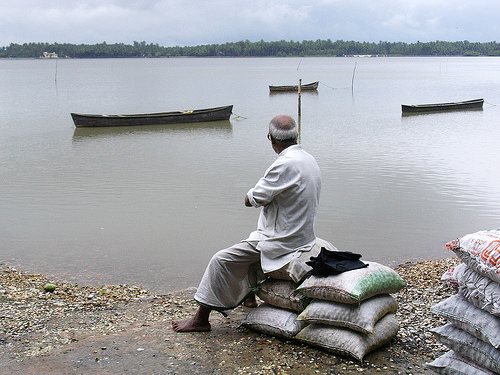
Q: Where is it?
A: This is at the lake.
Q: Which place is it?
A: It is a lake.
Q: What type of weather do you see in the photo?
A: It is cloudy.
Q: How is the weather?
A: It is cloudy.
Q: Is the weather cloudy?
A: Yes, it is cloudy.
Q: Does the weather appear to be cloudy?
A: Yes, it is cloudy.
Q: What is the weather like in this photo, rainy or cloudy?
A: It is cloudy.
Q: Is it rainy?
A: No, it is cloudy.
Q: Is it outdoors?
A: Yes, it is outdoors.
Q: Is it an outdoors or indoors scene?
A: It is outdoors.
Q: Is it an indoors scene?
A: No, it is outdoors.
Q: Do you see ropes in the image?
A: No, there are no ropes.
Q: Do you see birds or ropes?
A: No, there are no ropes or birds.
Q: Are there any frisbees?
A: No, there are no frisbees.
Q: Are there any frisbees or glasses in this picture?
A: No, there are no frisbees or glasses.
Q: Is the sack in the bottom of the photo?
A: Yes, the sack is in the bottom of the image.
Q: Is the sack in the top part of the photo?
A: No, the sack is in the bottom of the image.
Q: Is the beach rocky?
A: Yes, the beach is rocky.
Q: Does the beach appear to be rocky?
A: Yes, the beach is rocky.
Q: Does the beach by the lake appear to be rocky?
A: Yes, the beach is rocky.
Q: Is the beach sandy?
A: No, the beach is rocky.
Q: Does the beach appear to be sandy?
A: No, the beach is rocky.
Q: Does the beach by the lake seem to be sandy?
A: No, the beach is rocky.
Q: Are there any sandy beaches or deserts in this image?
A: No, there is a beach but it is rocky.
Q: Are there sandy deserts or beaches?
A: No, there is a beach but it is rocky.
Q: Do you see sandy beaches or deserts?
A: No, there is a beach but it is rocky.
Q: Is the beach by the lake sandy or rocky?
A: The beach is rocky.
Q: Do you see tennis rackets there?
A: No, there are no tennis rackets.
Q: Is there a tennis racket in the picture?
A: No, there are no rackets.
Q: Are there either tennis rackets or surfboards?
A: No, there are no tennis rackets or surfboards.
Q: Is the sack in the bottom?
A: Yes, the sack is in the bottom of the image.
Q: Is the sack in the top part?
A: No, the sack is in the bottom of the image.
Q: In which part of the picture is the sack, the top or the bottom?
A: The sack is in the bottom of the image.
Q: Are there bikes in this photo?
A: No, there are no bikes.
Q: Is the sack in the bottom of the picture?
A: Yes, the sack is in the bottom of the image.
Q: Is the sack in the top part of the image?
A: No, the sack is in the bottom of the image.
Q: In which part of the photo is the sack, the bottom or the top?
A: The sack is in the bottom of the image.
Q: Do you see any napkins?
A: No, there are no napkins.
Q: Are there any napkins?
A: No, there are no napkins.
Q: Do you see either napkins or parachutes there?
A: No, there are no napkins or parachutes.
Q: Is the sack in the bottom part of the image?
A: Yes, the sack is in the bottom of the image.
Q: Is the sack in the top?
A: No, the sack is in the bottom of the image.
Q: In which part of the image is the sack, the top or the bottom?
A: The sack is in the bottom of the image.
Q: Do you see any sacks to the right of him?
A: Yes, there is a sack to the right of the man.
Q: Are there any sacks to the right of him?
A: Yes, there is a sack to the right of the man.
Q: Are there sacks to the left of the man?
A: No, the sack is to the right of the man.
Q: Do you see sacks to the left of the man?
A: No, the sack is to the right of the man.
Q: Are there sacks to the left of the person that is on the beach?
A: No, the sack is to the right of the man.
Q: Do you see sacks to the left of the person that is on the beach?
A: No, the sack is to the right of the man.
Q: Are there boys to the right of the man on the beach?
A: No, there is a sack to the right of the man.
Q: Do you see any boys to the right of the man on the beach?
A: No, there is a sack to the right of the man.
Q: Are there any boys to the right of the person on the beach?
A: No, there is a sack to the right of the man.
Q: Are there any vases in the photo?
A: No, there are no vases.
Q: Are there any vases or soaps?
A: No, there are no vases or soaps.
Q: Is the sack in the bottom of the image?
A: Yes, the sack is in the bottom of the image.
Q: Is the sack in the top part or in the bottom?
A: The sack is in the bottom of the image.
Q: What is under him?
A: The sack is under the man.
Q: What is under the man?
A: The sack is under the man.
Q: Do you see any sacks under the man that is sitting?
A: Yes, there is a sack under the man.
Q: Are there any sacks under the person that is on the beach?
A: Yes, there is a sack under the man.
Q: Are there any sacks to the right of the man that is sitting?
A: Yes, there is a sack to the right of the man.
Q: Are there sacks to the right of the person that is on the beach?
A: Yes, there is a sack to the right of the man.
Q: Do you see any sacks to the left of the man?
A: No, the sack is to the right of the man.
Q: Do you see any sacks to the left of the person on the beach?
A: No, the sack is to the right of the man.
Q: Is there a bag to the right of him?
A: No, there is a sack to the right of the man.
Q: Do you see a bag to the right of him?
A: No, there is a sack to the right of the man.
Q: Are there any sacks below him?
A: Yes, there is a sack below the man.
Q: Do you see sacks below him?
A: Yes, there is a sack below the man.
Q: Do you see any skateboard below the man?
A: No, there is a sack below the man.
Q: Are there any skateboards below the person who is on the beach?
A: No, there is a sack below the man.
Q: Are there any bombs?
A: No, there are no bombs.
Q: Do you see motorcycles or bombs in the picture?
A: No, there are no bombs or motorcycles.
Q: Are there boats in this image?
A: Yes, there is a boat.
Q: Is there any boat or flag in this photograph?
A: Yes, there is a boat.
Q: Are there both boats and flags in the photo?
A: No, there is a boat but no flags.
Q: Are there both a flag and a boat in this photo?
A: No, there is a boat but no flags.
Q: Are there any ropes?
A: No, there are no ropes.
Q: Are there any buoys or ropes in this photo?
A: No, there are no ropes or buoys.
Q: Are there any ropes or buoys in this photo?
A: No, there are no ropes or buoys.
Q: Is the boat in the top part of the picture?
A: Yes, the boat is in the top of the image.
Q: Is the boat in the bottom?
A: No, the boat is in the top of the image.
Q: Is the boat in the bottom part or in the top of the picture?
A: The boat is in the top of the image.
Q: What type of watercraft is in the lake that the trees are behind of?
A: The watercraft is a boat.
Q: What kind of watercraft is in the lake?
A: The watercraft is a boat.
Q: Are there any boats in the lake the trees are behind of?
A: Yes, there is a boat in the lake.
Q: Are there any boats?
A: Yes, there is a boat.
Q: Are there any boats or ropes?
A: Yes, there is a boat.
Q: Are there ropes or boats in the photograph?
A: Yes, there is a boat.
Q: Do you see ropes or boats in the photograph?
A: Yes, there is a boat.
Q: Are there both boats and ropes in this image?
A: No, there is a boat but no ropes.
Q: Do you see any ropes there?
A: No, there are no ropes.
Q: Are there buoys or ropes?
A: No, there are no ropes or buoys.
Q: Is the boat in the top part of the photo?
A: Yes, the boat is in the top of the image.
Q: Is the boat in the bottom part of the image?
A: No, the boat is in the top of the image.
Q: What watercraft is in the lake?
A: The watercraft is a boat.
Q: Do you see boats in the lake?
A: Yes, there is a boat in the lake.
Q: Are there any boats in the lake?
A: Yes, there is a boat in the lake.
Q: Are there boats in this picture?
A: Yes, there is a boat.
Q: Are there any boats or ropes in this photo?
A: Yes, there is a boat.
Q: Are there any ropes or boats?
A: Yes, there is a boat.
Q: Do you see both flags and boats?
A: No, there is a boat but no flags.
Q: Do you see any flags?
A: No, there are no flags.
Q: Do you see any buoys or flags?
A: No, there are no flags or buoys.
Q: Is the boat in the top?
A: Yes, the boat is in the top of the image.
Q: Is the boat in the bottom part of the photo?
A: No, the boat is in the top of the image.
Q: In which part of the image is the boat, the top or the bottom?
A: The boat is in the top of the image.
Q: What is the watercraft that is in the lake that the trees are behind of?
A: The watercraft is a boat.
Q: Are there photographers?
A: No, there are no photographers.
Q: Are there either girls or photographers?
A: No, there are no photographers or girls.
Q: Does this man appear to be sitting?
A: Yes, the man is sitting.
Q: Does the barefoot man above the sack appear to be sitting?
A: Yes, the man is sitting.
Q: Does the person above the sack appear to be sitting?
A: Yes, the man is sitting.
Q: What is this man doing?
A: The man is sitting.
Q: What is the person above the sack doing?
A: The man is sitting.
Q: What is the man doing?
A: The man is sitting.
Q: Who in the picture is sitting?
A: The man is sitting.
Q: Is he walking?
A: No, the man is sitting.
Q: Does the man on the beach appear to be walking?
A: No, the man is sitting.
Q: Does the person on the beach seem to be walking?
A: No, the man is sitting.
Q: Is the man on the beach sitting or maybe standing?
A: The man is sitting.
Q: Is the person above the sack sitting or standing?
A: The man is sitting.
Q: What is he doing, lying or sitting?
A: The man is sitting.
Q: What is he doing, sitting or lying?
A: The man is sitting.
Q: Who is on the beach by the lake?
A: The man is on the beach.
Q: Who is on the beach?
A: The man is on the beach.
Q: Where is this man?
A: The man is on the beach.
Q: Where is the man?
A: The man is on the beach.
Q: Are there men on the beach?
A: Yes, there is a man on the beach.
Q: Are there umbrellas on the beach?
A: No, there is a man on the beach.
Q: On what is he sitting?
A: The man is sitting on the sack.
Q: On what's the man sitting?
A: The man is sitting on the sack.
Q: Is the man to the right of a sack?
A: No, the man is to the left of a sack.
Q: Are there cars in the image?
A: No, there are no cars.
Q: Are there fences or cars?
A: No, there are no cars or fences.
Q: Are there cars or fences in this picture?
A: No, there are no cars or fences.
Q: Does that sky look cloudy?
A: Yes, the sky is cloudy.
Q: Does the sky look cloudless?
A: No, the sky is cloudy.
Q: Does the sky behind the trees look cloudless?
A: No, the sky is cloudy.